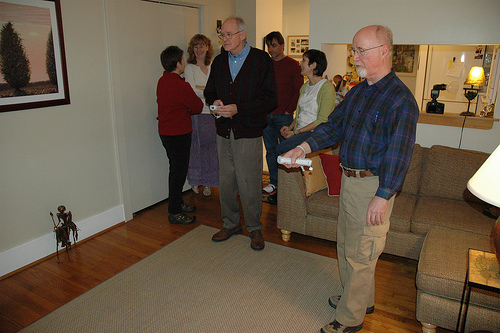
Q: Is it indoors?
A: Yes, it is indoors.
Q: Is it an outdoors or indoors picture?
A: It is indoors.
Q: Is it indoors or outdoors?
A: It is indoors.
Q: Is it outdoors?
A: No, it is indoors.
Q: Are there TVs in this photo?
A: No, there are no tvs.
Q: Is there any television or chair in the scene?
A: No, there are no televisions or chairs.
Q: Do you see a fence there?
A: No, there are no fences.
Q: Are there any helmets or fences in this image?
A: No, there are no fences or helmets.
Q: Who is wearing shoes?
A: The man is wearing shoes.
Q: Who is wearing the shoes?
A: The man is wearing shoes.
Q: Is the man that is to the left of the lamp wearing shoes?
A: Yes, the man is wearing shoes.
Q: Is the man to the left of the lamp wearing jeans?
A: No, the man is wearing shoes.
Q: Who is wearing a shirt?
A: The man is wearing a shirt.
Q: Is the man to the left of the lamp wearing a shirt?
A: Yes, the man is wearing a shirt.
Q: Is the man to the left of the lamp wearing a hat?
A: No, the man is wearing a shirt.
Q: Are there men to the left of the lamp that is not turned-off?
A: Yes, there is a man to the left of the lamp.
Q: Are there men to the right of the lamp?
A: No, the man is to the left of the lamp.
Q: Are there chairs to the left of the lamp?
A: No, there is a man to the left of the lamp.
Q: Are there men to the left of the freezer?
A: Yes, there is a man to the left of the freezer.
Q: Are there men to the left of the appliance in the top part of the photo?
A: Yes, there is a man to the left of the freezer.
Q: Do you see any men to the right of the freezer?
A: No, the man is to the left of the freezer.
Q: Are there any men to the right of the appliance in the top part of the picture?
A: No, the man is to the left of the freezer.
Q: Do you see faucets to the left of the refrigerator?
A: No, there is a man to the left of the refrigerator.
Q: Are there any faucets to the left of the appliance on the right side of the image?
A: No, there is a man to the left of the refrigerator.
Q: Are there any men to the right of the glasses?
A: Yes, there is a man to the right of the glasses.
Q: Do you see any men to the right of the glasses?
A: Yes, there is a man to the right of the glasses.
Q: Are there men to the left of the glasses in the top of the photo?
A: No, the man is to the right of the glasses.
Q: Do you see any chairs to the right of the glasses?
A: No, there is a man to the right of the glasses.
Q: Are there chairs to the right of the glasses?
A: No, there is a man to the right of the glasses.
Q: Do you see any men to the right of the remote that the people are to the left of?
A: Yes, there is a man to the right of the remote control.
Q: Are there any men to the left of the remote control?
A: No, the man is to the right of the remote control.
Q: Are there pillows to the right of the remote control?
A: No, there is a man to the right of the remote control.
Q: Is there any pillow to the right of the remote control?
A: No, there is a man to the right of the remote control.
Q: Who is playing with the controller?
A: The man is playing with the controller.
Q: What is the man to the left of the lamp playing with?
A: The man is playing with a controller.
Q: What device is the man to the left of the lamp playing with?
A: The man is playing with a controller.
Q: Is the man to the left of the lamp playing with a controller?
A: Yes, the man is playing with a controller.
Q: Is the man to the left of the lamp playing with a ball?
A: No, the man is playing with a controller.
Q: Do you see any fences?
A: No, there are no fences.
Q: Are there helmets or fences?
A: No, there are no fences or helmets.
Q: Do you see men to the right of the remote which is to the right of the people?
A: Yes, there is a man to the right of the remote control.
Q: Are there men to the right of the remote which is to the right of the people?
A: Yes, there is a man to the right of the remote control.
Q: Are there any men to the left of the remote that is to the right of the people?
A: No, the man is to the right of the remote.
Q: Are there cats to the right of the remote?
A: No, there is a man to the right of the remote.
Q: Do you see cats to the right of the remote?
A: No, there is a man to the right of the remote.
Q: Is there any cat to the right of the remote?
A: No, there is a man to the right of the remote.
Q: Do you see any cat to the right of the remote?
A: No, there is a man to the right of the remote.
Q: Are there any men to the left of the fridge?
A: Yes, there is a man to the left of the fridge.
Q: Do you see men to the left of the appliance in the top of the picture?
A: Yes, there is a man to the left of the fridge.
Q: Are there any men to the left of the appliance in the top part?
A: Yes, there is a man to the left of the fridge.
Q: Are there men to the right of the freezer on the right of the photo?
A: No, the man is to the left of the refrigerator.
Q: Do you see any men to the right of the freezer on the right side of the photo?
A: No, the man is to the left of the refrigerator.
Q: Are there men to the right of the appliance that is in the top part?
A: No, the man is to the left of the refrigerator.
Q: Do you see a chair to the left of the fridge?
A: No, there is a man to the left of the fridge.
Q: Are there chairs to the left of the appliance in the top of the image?
A: No, there is a man to the left of the fridge.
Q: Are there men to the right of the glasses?
A: Yes, there is a man to the right of the glasses.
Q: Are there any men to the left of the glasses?
A: No, the man is to the right of the glasses.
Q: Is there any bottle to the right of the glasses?
A: No, there is a man to the right of the glasses.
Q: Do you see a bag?
A: No, there are no bags.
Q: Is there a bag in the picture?
A: No, there are no bags.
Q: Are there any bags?
A: No, there are no bags.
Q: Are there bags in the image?
A: No, there are no bags.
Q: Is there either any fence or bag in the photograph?
A: No, there are no bags or fences.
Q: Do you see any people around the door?
A: Yes, there are people around the door.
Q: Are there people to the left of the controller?
A: Yes, there are people to the left of the controller.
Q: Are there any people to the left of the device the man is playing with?
A: Yes, there are people to the left of the controller.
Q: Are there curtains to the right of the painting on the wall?
A: No, there are people to the right of the painting.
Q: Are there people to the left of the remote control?
A: Yes, there are people to the left of the remote control.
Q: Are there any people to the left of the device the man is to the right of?
A: Yes, there are people to the left of the remote control.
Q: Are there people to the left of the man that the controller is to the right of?
A: Yes, there are people to the left of the man.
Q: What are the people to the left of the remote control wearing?
A: The people are wearing a shirt.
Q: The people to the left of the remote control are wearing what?
A: The people are wearing a shirt.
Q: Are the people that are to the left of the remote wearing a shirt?
A: Yes, the people are wearing a shirt.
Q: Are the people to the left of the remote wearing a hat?
A: No, the people are wearing a shirt.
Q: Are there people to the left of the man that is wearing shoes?
A: Yes, there are people to the left of the man.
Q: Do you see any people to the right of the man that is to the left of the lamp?
A: No, the people are to the left of the man.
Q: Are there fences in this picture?
A: No, there are no fences.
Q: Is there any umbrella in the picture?
A: No, there are no umbrellas.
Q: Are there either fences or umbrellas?
A: No, there are no umbrellas or fences.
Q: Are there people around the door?
A: Yes, there are people around the door.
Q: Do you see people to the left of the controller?
A: Yes, there are people to the left of the controller.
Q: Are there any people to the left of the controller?
A: Yes, there are people to the left of the controller.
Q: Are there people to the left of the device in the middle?
A: Yes, there are people to the left of the controller.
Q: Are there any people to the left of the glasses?
A: Yes, there are people to the left of the glasses.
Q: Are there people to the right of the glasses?
A: No, the people are to the left of the glasses.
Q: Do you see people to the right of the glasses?
A: No, the people are to the left of the glasses.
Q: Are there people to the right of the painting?
A: Yes, there are people to the right of the painting.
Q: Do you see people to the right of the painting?
A: Yes, there are people to the right of the painting.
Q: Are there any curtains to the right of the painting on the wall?
A: No, there are people to the right of the painting.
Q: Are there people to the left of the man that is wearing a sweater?
A: Yes, there are people to the left of the man.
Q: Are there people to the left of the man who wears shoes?
A: Yes, there are people to the left of the man.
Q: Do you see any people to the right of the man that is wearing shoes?
A: No, the people are to the left of the man.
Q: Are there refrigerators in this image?
A: Yes, there is a refrigerator.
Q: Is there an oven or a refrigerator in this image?
A: Yes, there is a refrigerator.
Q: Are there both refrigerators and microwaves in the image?
A: No, there is a refrigerator but no microwaves.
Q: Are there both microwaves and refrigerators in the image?
A: No, there is a refrigerator but no microwaves.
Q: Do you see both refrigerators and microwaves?
A: No, there is a refrigerator but no microwaves.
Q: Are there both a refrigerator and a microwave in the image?
A: No, there is a refrigerator but no microwaves.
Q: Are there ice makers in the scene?
A: No, there are no ice makers.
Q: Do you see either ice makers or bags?
A: No, there are no ice makers or bags.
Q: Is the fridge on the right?
A: Yes, the fridge is on the right of the image.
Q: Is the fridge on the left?
A: No, the fridge is on the right of the image.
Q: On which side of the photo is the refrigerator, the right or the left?
A: The refrigerator is on the right of the image.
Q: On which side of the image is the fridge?
A: The fridge is on the right of the image.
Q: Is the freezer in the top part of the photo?
A: Yes, the freezer is in the top of the image.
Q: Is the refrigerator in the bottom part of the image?
A: No, the refrigerator is in the top of the image.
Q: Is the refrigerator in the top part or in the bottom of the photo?
A: The refrigerator is in the top of the image.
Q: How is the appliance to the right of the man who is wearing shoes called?
A: The appliance is a refrigerator.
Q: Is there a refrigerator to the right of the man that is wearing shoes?
A: Yes, there is a refrigerator to the right of the man.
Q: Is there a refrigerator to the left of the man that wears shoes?
A: No, the refrigerator is to the right of the man.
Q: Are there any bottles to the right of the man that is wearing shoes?
A: No, there is a refrigerator to the right of the man.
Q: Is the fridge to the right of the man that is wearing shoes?
A: Yes, the fridge is to the right of the man.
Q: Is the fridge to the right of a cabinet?
A: No, the fridge is to the right of the man.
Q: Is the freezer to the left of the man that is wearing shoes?
A: No, the freezer is to the right of the man.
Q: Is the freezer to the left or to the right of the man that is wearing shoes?
A: The freezer is to the right of the man.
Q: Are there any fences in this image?
A: No, there are no fences.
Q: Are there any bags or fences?
A: No, there are no fences or bags.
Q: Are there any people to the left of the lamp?
A: Yes, there are people to the left of the lamp.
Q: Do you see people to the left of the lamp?
A: Yes, there are people to the left of the lamp.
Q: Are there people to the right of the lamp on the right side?
A: No, the people are to the left of the lamp.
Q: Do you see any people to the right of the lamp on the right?
A: No, the people are to the left of the lamp.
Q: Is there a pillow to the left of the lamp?
A: No, there are people to the left of the lamp.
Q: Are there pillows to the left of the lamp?
A: No, there are people to the left of the lamp.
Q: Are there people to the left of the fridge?
A: Yes, there are people to the left of the fridge.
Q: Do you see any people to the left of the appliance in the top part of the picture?
A: Yes, there are people to the left of the fridge.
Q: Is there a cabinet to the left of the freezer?
A: No, there are people to the left of the freezer.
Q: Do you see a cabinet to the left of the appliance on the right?
A: No, there are people to the left of the freezer.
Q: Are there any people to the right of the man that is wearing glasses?
A: Yes, there are people to the right of the man.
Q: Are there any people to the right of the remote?
A: Yes, there are people to the right of the remote.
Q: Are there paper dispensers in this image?
A: No, there are no paper dispensers.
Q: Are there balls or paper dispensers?
A: No, there are no paper dispensers or balls.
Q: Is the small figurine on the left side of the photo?
A: Yes, the figurine is on the left of the image.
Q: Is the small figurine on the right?
A: No, the figurine is on the left of the image.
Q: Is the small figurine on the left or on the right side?
A: The figurine is on the left of the image.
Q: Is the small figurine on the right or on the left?
A: The figurine is on the left of the image.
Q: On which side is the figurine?
A: The figurine is on the left of the image.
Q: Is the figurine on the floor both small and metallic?
A: Yes, the figurine is small and metallic.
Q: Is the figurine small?
A: Yes, the figurine is small.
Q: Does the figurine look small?
A: Yes, the figurine is small.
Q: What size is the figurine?
A: The figurine is small.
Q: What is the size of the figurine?
A: The figurine is small.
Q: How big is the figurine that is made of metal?
A: The figurine is small.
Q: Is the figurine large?
A: No, the figurine is small.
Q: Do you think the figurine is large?
A: No, the figurine is small.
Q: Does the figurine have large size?
A: No, the figurine is small.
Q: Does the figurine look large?
A: No, the figurine is small.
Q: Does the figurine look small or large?
A: The figurine is small.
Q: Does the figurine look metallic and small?
A: Yes, the figurine is metallic and small.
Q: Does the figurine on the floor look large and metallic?
A: No, the figurine is metallic but small.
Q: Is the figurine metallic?
A: Yes, the figurine is metallic.